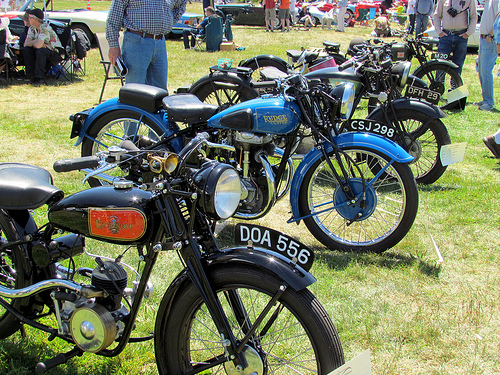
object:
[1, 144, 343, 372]
black motorcycle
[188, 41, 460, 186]
black motorcycle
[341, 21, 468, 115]
black motorcycle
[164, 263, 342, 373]
tire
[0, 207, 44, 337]
tire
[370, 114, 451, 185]
tire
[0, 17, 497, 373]
grassy meadow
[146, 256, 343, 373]
wheel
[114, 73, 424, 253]
motorcycle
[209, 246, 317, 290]
tire rim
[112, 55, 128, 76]
magazine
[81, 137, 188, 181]
horn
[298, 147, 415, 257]
wheel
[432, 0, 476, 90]
man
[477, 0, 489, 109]
man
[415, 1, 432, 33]
man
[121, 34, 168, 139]
jeans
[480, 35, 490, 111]
jeans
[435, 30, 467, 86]
jeans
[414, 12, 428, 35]
jeans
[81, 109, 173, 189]
tire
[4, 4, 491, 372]
grass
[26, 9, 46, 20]
cap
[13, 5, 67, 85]
person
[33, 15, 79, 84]
chair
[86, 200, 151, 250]
logo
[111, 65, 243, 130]
seat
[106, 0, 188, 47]
shirt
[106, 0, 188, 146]
man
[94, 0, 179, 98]
person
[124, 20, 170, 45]
belt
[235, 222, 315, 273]
license plate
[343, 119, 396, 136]
license plate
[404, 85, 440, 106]
license plate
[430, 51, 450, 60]
license plate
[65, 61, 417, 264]
bike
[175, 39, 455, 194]
bike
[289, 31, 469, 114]
bike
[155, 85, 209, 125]
seat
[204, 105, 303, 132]
motor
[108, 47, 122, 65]
hand